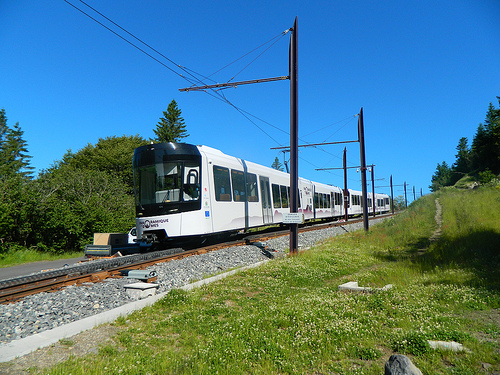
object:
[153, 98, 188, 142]
tree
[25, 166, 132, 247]
tree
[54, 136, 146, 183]
tree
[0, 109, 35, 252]
tree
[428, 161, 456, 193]
tree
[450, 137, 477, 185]
tree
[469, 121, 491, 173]
tree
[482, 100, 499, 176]
tree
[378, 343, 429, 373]
log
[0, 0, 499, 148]
sky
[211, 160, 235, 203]
window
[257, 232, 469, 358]
field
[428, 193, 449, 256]
strip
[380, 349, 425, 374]
rock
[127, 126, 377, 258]
train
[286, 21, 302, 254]
pole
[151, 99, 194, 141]
trees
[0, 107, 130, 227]
trees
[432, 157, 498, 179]
trees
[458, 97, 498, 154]
trees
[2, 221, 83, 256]
trees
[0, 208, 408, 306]
tracks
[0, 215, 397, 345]
pebbles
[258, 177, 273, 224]
door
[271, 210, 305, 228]
sign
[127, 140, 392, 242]
bus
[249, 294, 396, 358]
flowers